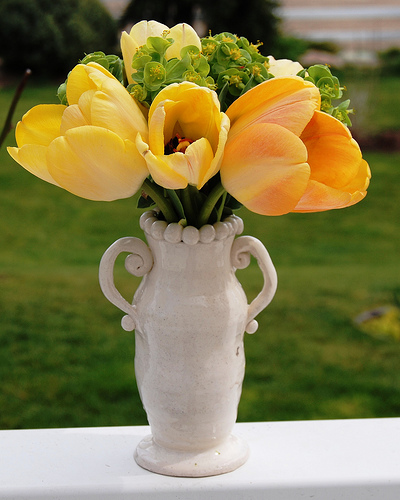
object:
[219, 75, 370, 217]
flower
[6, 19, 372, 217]
tulips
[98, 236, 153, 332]
handle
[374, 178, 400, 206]
ground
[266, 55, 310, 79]
yellow flower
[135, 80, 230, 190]
flower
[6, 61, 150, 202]
flower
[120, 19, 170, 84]
flowers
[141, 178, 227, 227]
green stems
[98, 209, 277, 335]
nector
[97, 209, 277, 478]
vase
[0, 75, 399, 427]
grass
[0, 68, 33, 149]
twig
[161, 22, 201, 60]
flower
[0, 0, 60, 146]
hedges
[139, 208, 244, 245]
balls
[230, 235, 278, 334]
handle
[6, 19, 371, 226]
bouquet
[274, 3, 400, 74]
wall